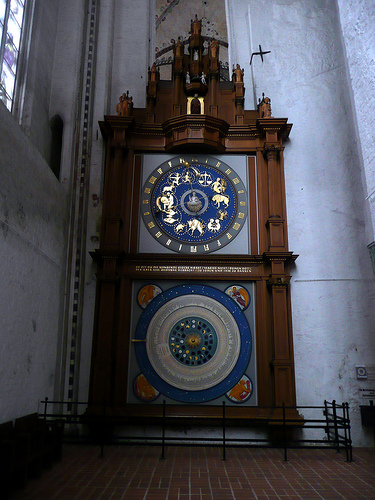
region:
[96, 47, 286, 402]
this is a board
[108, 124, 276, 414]
the board is tall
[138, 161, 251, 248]
this is a clock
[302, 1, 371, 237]
the walls are white in color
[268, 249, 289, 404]
the pillars are straight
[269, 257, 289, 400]
the pillar is brown in color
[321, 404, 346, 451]
this is a grilled fence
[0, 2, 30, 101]
the window is closed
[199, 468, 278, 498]
the floor is made of bricks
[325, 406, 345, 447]
the grilled fence is black in color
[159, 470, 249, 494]
this is the floor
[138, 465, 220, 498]
the floor is made of tiles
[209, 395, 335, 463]
this is a fence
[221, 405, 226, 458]
this is a grill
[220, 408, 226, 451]
the grill is metallic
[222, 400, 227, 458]
the grill is black in color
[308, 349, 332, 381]
this is the wall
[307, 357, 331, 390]
the wall is white in color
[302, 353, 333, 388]
the wall is made of stone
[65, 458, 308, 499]
Dark red tiled floor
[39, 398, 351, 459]
Black fence enclosing the artistic structure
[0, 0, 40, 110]
Window high up on the wall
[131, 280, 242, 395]
Entire blue circular rim in the bottom portion of the structure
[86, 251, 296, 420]
Entire brown square enclosing the bottom portion of the structure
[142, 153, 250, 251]
Circular portion of the upper half of the structure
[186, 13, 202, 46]
Uppermost piece of the structure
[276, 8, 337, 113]
White wall to the right of the top of the structure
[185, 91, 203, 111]
Statue towards the top backed by yellow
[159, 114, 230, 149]
Brown semi-circle platform jutting out at the top of the structure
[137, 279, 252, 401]
Orange, blue white and gold decoration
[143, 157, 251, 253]
Gold, blue and gray astrological decoration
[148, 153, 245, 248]
Large astrological decoration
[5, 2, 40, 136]
Purple stained glass window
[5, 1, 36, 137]
Stained glass window in old building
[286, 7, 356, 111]
Gray wall in old building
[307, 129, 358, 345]
Gray wall in old building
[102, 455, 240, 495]
Red brick floor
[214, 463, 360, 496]
Red brick floor in old building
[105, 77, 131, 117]
Brown wooden figure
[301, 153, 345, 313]
this is a wall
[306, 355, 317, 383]
the wall is white in color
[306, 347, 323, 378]
the wall is made of stone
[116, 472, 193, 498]
this is the floor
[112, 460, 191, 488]
the floor is made of tiles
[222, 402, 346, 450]
this is a grill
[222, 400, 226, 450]
the grills are metallic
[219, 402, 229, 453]
the grill is black in color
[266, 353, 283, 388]
the frame is wooden